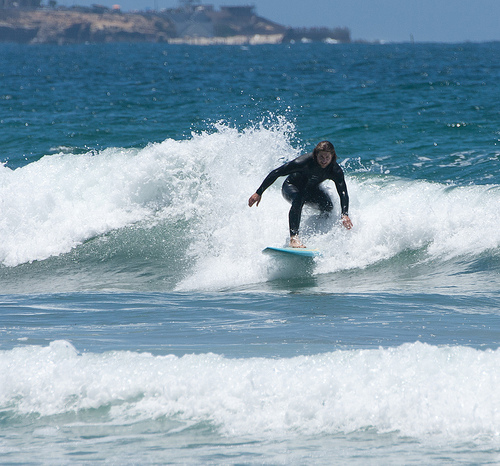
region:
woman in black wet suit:
[248, 135, 358, 250]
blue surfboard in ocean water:
[254, 212, 349, 265]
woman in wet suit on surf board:
[251, 137, 357, 272]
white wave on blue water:
[5, 104, 493, 304]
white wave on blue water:
[3, 330, 498, 440]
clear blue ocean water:
[1, 39, 496, 454]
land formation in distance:
[3, 5, 348, 47]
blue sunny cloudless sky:
[256, 0, 496, 52]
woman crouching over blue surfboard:
[246, 141, 359, 277]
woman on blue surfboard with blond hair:
[247, 133, 358, 271]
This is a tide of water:
[4, 146, 47, 275]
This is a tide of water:
[42, 135, 112, 282]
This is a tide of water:
[113, 139, 200, 293]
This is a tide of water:
[179, 118, 244, 306]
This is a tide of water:
[215, 110, 260, 282]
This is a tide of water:
[359, 148, 426, 295]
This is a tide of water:
[416, 160, 493, 340]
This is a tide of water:
[13, 290, 155, 444]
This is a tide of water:
[164, 318, 294, 449]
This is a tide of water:
[289, 331, 384, 458]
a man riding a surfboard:
[251, 146, 383, 273]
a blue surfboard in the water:
[245, 240, 320, 260]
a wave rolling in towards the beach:
[29, 326, 474, 444]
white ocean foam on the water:
[125, 289, 448, 339]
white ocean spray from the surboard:
[218, 130, 280, 227]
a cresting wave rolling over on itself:
[38, 147, 234, 220]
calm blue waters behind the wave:
[321, 34, 460, 126]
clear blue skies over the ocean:
[353, 0, 470, 35]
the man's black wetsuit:
[266, 155, 352, 240]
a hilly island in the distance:
[74, 1, 331, 50]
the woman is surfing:
[253, 128, 367, 276]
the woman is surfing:
[212, 75, 418, 310]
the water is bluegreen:
[30, 60, 64, 95]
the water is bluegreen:
[113, 25, 200, 105]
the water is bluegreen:
[351, 64, 440, 151]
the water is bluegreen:
[48, 83, 153, 123]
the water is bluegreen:
[93, 65, 143, 139]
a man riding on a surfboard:
[228, 134, 386, 286]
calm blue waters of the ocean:
[306, 48, 443, 123]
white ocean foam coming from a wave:
[114, 360, 394, 429]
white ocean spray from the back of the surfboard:
[201, 121, 276, 208]